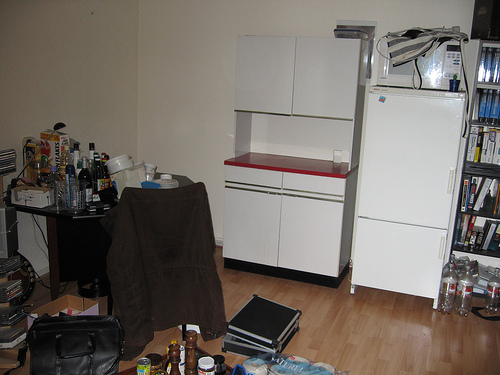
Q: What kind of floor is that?
A: A wooden floor.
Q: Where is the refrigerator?
A: Against the wall.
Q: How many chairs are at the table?
A: 1 chair.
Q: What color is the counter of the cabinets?
A: The countertop is red.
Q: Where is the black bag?
A: On the floor.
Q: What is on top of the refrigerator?
A: A microwave.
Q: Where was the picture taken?
A: In a kitchen space.